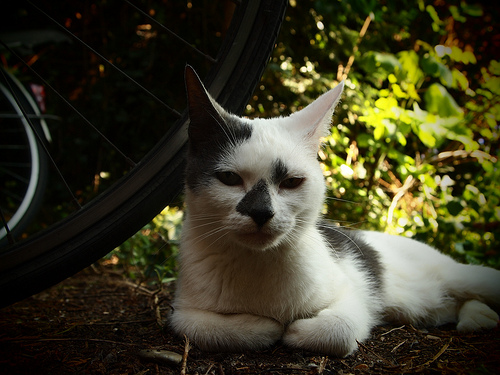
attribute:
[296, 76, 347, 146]
ear — white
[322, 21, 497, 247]
trees — green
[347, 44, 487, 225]
bush — green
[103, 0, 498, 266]
trees — Green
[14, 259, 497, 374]
ground — dirty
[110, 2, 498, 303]
trees — Green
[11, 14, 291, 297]
bicycle — second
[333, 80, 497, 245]
shrubbery — background , in the sun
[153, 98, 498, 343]
cat — white,  gray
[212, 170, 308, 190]
eyes — gentle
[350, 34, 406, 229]
tree — Green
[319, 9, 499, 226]
shrubbery — green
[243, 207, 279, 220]
nose — gray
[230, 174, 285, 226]
patch — triangular , gray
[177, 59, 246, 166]
ear — gray 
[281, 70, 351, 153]
ear — white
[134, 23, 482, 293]
trees — green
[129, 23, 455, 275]
trees — green